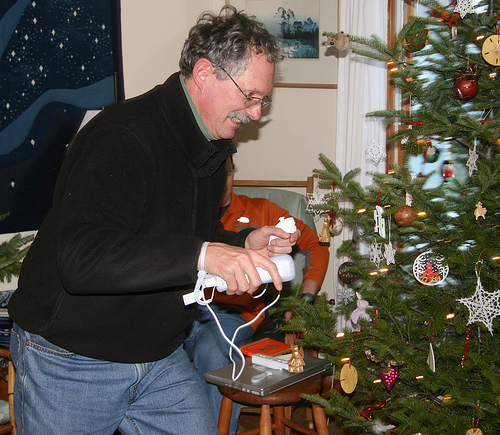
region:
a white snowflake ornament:
[456, 267, 498, 337]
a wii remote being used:
[180, 213, 297, 383]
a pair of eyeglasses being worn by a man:
[216, 59, 271, 116]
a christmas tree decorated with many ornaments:
[253, 0, 498, 433]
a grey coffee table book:
[201, 342, 336, 402]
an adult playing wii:
[6, 32, 299, 434]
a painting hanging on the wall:
[223, 0, 320, 58]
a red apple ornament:
[453, 47, 482, 99]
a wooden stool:
[213, 351, 335, 434]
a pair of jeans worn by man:
[10, 310, 227, 432]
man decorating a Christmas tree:
[40, 32, 405, 432]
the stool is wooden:
[237, 390, 332, 428]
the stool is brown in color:
[230, 397, 320, 432]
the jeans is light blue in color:
[18, 356, 218, 432]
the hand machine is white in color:
[193, 253, 295, 293]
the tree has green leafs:
[391, 56, 498, 334]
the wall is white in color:
[120, 24, 190, 72]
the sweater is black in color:
[33, 143, 173, 326]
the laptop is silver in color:
[210, 361, 347, 392]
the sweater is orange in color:
[236, 193, 318, 250]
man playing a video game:
[12, 3, 317, 433]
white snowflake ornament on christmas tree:
[457, 265, 498, 335]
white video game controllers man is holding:
[179, 216, 299, 313]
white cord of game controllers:
[202, 291, 277, 383]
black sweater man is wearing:
[14, 85, 239, 350]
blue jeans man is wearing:
[5, 325, 210, 434]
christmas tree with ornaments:
[297, 6, 497, 433]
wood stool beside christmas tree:
[204, 378, 329, 433]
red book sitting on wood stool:
[235, 335, 295, 362]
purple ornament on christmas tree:
[377, 363, 400, 390]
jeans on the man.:
[34, 386, 80, 423]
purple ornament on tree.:
[375, 364, 400, 399]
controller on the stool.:
[252, 353, 287, 375]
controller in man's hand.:
[272, 208, 296, 246]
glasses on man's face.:
[221, 69, 268, 108]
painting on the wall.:
[288, 9, 310, 55]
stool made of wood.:
[260, 408, 272, 433]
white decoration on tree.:
[465, 293, 497, 332]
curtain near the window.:
[339, 77, 374, 127]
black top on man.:
[119, 150, 164, 212]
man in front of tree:
[3, 8, 360, 430]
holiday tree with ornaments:
[303, 8, 490, 431]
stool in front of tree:
[215, 372, 324, 434]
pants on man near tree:
[4, 311, 218, 433]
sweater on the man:
[18, 85, 243, 345]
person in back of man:
[216, 147, 328, 374]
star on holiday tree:
[456, 278, 498, 321]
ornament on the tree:
[374, 363, 399, 390]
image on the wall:
[236, 3, 330, 58]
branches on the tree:
[364, 64, 499, 141]